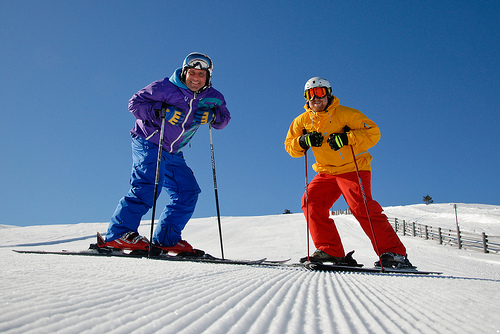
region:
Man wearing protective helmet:
[297, 73, 338, 94]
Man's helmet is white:
[294, 70, 344, 94]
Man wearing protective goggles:
[295, 82, 340, 102]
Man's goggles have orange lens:
[293, 84, 335, 100]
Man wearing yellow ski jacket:
[268, 100, 390, 176]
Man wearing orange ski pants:
[301, 163, 405, 258]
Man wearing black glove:
[293, 125, 328, 152]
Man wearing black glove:
[324, 127, 356, 157]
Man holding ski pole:
[334, 118, 389, 254]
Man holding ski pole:
[290, 146, 322, 265]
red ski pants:
[295, 161, 405, 267]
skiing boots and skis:
[274, 238, 444, 283]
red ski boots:
[80, 203, 235, 270]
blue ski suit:
[87, 59, 239, 251]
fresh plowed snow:
[62, 260, 254, 331]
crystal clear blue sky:
[8, 6, 135, 87]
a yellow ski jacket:
[276, 80, 388, 172]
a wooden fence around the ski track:
[385, 191, 497, 266]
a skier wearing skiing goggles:
[286, 75, 341, 105]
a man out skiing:
[82, 47, 236, 291]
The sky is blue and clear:
[220, 10, 355, 80]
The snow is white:
[105, 270, 236, 327]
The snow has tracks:
[160, 263, 268, 318]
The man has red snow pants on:
[278, 168, 474, 293]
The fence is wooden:
[392, 213, 492, 276]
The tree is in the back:
[413, 185, 473, 237]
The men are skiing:
[55, 202, 360, 309]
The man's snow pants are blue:
[123, 132, 204, 282]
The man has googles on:
[291, 70, 363, 118]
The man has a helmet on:
[296, 60, 326, 94]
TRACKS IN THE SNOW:
[136, 286, 416, 328]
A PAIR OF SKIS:
[15, 236, 295, 273]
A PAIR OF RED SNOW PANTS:
[295, 168, 405, 260]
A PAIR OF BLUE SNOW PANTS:
[111, 141, 203, 245]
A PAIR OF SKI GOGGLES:
[301, 82, 331, 102]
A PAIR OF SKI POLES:
[145, 103, 235, 259]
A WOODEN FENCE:
[394, 206, 498, 254]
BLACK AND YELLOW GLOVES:
[295, 126, 355, 153]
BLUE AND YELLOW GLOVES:
[164, 97, 221, 133]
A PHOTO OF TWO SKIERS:
[38, 41, 464, 293]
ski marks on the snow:
[96, 265, 412, 330]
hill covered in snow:
[222, 188, 324, 256]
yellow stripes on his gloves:
[283, 132, 363, 153]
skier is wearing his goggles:
[297, 71, 347, 111]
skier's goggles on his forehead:
[181, 42, 224, 82]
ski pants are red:
[302, 181, 425, 255]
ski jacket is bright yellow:
[285, 113, 400, 163]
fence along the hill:
[406, 205, 498, 260]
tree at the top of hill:
[417, 182, 448, 213]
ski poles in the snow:
[138, 101, 423, 284]